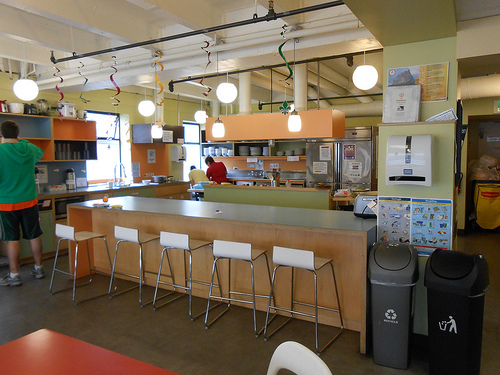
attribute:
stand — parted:
[327, 192, 342, 210]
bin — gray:
[353, 220, 416, 361]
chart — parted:
[387, 199, 450, 251]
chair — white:
[266, 336, 337, 372]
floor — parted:
[90, 327, 107, 333]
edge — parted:
[64, 202, 83, 218]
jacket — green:
[13, 150, 18, 164]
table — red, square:
[10, 349, 82, 359]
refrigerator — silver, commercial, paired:
[358, 142, 365, 155]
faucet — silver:
[111, 159, 135, 177]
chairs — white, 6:
[62, 220, 337, 328]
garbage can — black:
[433, 251, 485, 344]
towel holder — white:
[419, 141, 426, 145]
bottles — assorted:
[52, 142, 96, 158]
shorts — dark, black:
[5, 205, 54, 245]